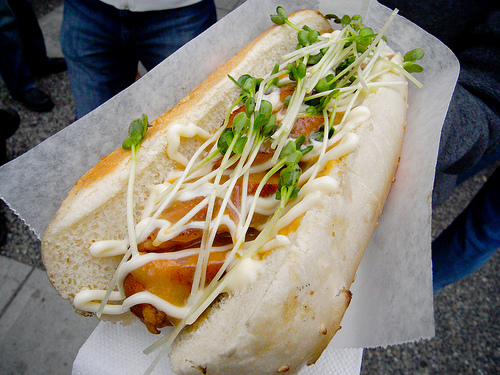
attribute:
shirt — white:
[81, 0, 214, 18]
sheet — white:
[6, 8, 460, 371]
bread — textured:
[142, 105, 382, 310]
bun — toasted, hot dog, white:
[40, 8, 407, 372]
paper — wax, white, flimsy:
[9, 0, 464, 365]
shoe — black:
[2, 76, 57, 116]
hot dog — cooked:
[96, 13, 387, 305]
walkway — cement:
[11, 3, 493, 370]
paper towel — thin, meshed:
[64, 314, 368, 374]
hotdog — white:
[40, 9, 410, 372]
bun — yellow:
[35, 47, 447, 348]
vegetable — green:
[124, 117, 151, 257]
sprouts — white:
[324, 12, 381, 72]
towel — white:
[71, 320, 360, 374]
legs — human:
[61, 19, 147, 85]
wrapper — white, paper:
[3, 2, 485, 345]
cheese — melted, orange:
[136, 251, 229, 311]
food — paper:
[40, 32, 414, 317]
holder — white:
[325, 54, 463, 354]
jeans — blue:
[60, 0, 220, 120]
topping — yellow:
[133, 259, 268, 339]